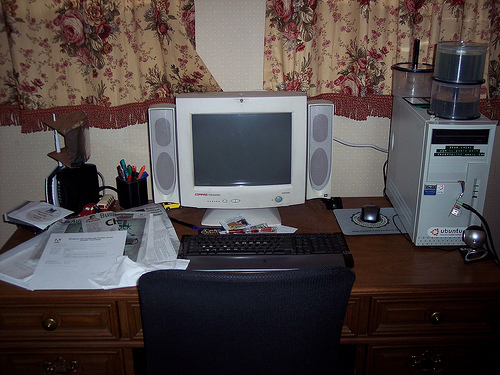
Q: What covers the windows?
A: Curtains.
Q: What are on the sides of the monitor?
A: Speakers.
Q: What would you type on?
A: Keyboard.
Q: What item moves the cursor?
A: Mouse.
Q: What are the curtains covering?
A: Windows.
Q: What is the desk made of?
A: Wood.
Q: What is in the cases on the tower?
A: CD's.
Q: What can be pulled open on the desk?
A: Drawers.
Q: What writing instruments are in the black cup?
A: Pens.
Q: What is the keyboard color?
A: Black.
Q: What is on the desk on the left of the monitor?
A: Assorted papers.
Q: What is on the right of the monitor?
A: A computer tower.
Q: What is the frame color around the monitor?
A: White.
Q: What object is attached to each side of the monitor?
A: Speaker.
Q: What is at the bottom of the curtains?
A: Fringe.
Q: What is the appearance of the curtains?
A: A flowered pattern.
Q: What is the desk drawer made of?
A: Wood.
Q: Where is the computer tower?
A: On the right of the desk.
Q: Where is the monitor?
A: Middle of the desk.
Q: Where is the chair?
A: In front of the desk.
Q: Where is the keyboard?
A: In front of the monitor.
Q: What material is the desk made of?
A: Wood.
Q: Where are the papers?
A: Left of the keyboard.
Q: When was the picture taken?
A: During the day.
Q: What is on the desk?
A: Computer.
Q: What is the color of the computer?
A: White.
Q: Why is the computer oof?
A: No one is using.